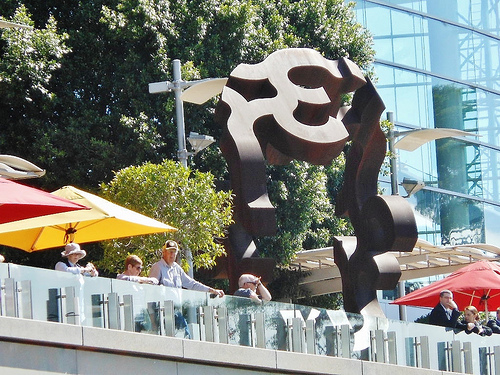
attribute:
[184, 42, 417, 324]
sculpture — brown, modern, metal, large, black, odd, wooden, carved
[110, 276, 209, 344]
panel — glass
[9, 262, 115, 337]
panel — glass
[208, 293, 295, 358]
panel — glass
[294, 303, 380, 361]
panel — glass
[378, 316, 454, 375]
panel — glass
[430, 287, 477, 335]
man — looking, standing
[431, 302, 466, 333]
suit — black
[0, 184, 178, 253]
umbrella — open, yellow, large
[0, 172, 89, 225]
umbrella — red, large, open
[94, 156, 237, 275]
tree — leafy, small, green, bright green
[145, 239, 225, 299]
man — tall, looking, standing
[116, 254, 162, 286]
woman — looking, standing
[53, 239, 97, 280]
woman — looking, standing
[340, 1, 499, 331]
building — glass, tall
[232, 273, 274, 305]
man — looking, standing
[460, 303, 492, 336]
person — standing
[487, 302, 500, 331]
person — standing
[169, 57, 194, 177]
light pole — tall